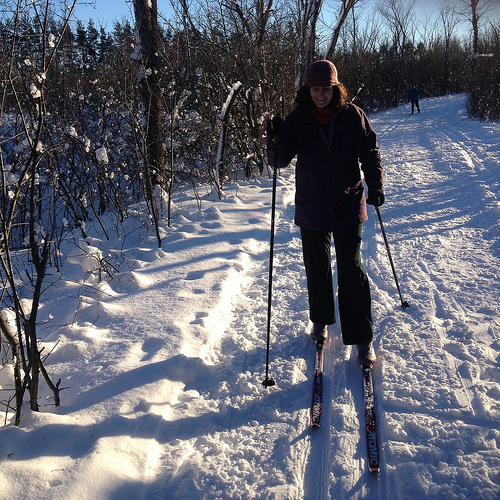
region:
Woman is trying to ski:
[237, 53, 426, 497]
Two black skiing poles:
[252, 137, 417, 404]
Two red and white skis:
[263, 275, 384, 497]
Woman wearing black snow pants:
[285, 190, 392, 387]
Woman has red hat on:
[307, 54, 349, 99]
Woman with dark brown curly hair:
[232, 57, 445, 484]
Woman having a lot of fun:
[247, 57, 435, 478]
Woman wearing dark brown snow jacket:
[242, 77, 402, 263]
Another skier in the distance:
[394, 75, 448, 138]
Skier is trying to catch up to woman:
[381, 62, 438, 127]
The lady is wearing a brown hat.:
[276, 50, 341, 94]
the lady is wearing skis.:
[303, 288, 393, 462]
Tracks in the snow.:
[400, 190, 496, 445]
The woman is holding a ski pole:
[255, 113, 287, 385]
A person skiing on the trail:
[395, 66, 456, 148]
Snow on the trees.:
[38, 69, 230, 187]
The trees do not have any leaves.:
[39, 55, 138, 205]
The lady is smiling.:
[291, 85, 354, 113]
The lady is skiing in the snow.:
[259, 35, 399, 385]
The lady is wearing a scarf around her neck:
[286, 99, 346, 130]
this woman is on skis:
[245, 55, 452, 475]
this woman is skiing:
[256, 30, 433, 486]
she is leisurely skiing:
[231, 25, 498, 483]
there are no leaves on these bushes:
[7, 2, 273, 379]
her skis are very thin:
[293, 342, 409, 498]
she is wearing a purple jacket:
[258, 45, 393, 244]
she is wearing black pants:
[293, 218, 395, 352]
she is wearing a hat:
[288, 42, 396, 337]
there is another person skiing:
[388, 66, 450, 144]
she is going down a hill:
[228, 37, 463, 486]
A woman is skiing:
[248, 51, 419, 482]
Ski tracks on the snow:
[293, 415, 393, 496]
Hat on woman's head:
[286, 53, 347, 114]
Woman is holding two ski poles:
[253, 53, 415, 397]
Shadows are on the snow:
[2, 93, 497, 498]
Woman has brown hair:
[290, 54, 351, 114]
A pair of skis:
[298, 318, 392, 486]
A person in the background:
[398, 74, 432, 124]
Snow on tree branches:
[3, 23, 221, 277]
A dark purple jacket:
[258, 100, 393, 234]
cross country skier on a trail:
[404, 90, 427, 120]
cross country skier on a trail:
[259, 56, 415, 477]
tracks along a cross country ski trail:
[389, 126, 491, 481]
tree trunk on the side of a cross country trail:
[123, 0, 171, 190]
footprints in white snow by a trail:
[131, 208, 209, 462]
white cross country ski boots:
[308, 315, 383, 370]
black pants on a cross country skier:
[293, 203, 380, 346]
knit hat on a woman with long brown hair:
[291, 56, 353, 121]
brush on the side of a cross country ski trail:
[46, 46, 261, 182]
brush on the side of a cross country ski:
[461, 35, 496, 126]